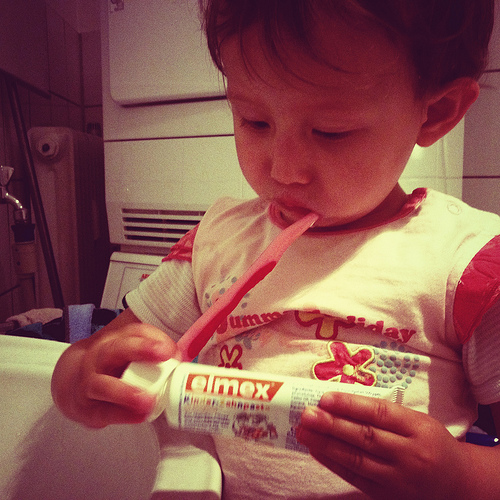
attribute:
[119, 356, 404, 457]
toothpaste — open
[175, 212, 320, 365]
toothbrush — red, pink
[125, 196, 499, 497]
shirt — white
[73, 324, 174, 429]
hand — brown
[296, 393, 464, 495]
hand — brown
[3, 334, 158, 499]
sink — white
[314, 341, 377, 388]
flower — red, yellow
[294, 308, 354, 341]
flower — yellow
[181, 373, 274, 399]
writing — white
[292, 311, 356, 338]
border — red